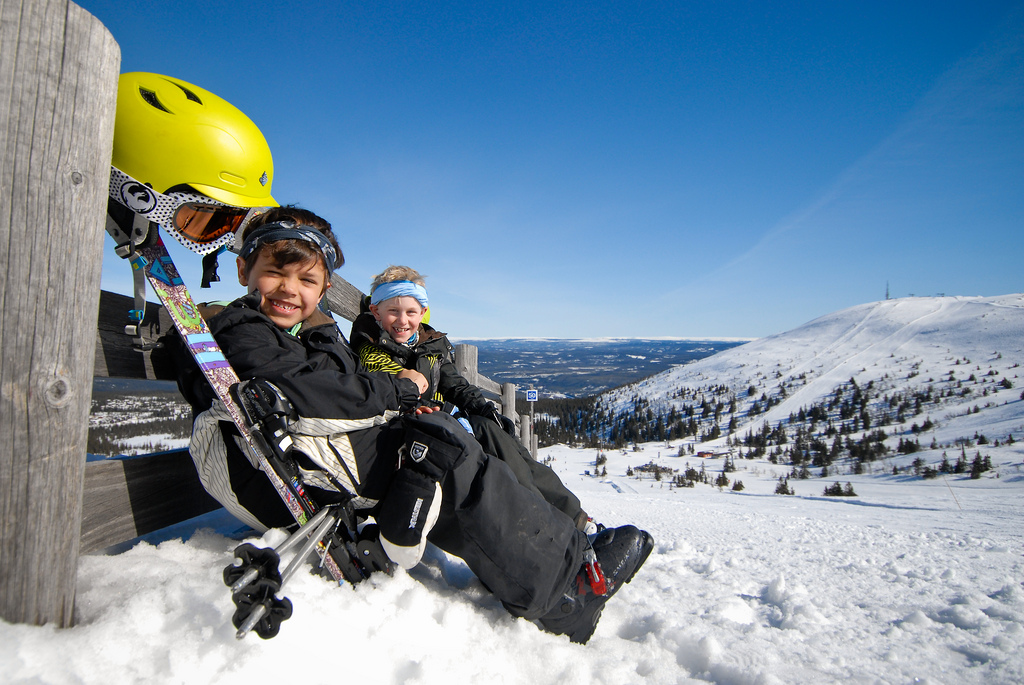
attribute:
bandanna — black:
[255, 215, 338, 282]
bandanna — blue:
[376, 268, 426, 357]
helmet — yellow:
[128, 31, 273, 235]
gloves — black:
[404, 361, 487, 506]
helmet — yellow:
[106, 48, 277, 271]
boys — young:
[208, 201, 604, 586]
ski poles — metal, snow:
[189, 513, 343, 639]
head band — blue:
[374, 266, 429, 301]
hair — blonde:
[357, 223, 535, 362]